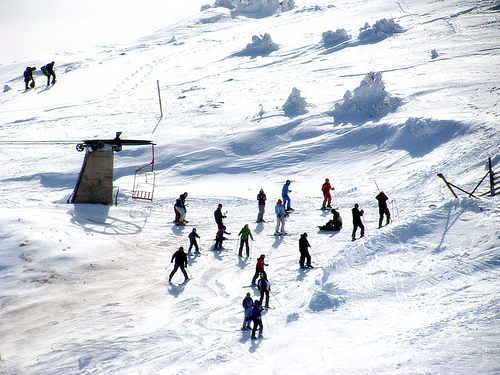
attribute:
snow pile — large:
[326, 63, 411, 135]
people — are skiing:
[160, 168, 408, 358]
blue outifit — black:
[241, 296, 253, 328]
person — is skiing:
[373, 192, 392, 229]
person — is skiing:
[347, 204, 365, 239]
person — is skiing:
[296, 232, 311, 269]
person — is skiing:
[237, 224, 254, 259]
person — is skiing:
[166, 246, 188, 284]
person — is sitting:
[317, 207, 344, 243]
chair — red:
[136, 175, 154, 201]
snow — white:
[0, 3, 499, 373]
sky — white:
[3, 4, 184, 46]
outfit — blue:
[279, 185, 294, 210]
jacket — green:
[235, 230, 260, 240]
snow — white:
[176, 80, 304, 195]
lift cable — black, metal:
[2, 135, 85, 152]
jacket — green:
[234, 228, 251, 236]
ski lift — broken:
[68, 134, 158, 209]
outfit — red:
[318, 174, 338, 212]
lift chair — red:
[129, 138, 161, 203]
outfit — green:
[238, 225, 249, 265]